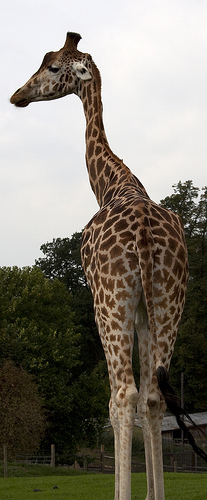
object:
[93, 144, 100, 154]
spot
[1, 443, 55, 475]
poles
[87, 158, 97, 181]
spot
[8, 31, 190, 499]
giraffe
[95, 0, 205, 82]
cloud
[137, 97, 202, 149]
cloud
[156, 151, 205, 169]
cloud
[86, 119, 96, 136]
spot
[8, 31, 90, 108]
giraffe head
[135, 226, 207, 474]
tail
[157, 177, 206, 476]
trees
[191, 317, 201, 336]
leaves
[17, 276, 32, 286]
leaves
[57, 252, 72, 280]
leaves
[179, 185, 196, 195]
leaves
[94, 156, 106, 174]
spot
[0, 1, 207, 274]
sky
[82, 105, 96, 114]
spot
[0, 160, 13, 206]
white clouds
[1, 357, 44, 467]
tree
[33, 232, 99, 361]
tree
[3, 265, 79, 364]
leaves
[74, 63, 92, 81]
ear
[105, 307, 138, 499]
leg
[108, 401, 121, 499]
leg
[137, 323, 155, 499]
leg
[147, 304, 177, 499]
leg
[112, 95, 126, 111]
clouds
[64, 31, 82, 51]
ossicone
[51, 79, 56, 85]
spot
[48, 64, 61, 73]
giraffe/eye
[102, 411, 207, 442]
roof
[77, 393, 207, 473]
building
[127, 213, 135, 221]
brown spot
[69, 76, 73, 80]
brown spot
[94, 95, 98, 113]
brown spot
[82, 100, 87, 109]
brown spot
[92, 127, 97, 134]
brown spot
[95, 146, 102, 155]
brown spot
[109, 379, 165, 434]
knees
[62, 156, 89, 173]
cloud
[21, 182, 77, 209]
cloud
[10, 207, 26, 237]
cloud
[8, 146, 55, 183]
cloud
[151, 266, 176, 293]
spot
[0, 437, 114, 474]
fence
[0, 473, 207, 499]
ground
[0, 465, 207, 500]
grass